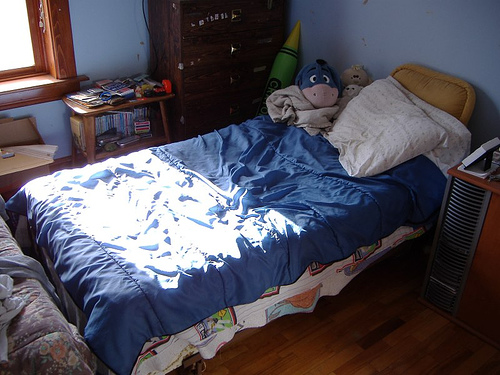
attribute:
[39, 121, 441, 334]
comforter — blue 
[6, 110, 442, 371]
comforter — blue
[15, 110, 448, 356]
mattress — blue 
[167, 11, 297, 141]
dresser — dark brown, tall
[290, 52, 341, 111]
eeyore doll — stuffed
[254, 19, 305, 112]
crayon — large, yellow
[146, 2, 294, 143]
dresser — brown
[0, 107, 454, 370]
bed — child's, messy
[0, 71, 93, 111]
window sill — brown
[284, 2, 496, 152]
wall — blue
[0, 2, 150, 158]
wall — blue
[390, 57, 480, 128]
pillow — yellow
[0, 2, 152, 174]
wall — blue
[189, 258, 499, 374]
flooring — wooden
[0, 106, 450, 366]
sheets — blue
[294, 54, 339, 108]
animal — stuffed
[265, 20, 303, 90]
crayon — oversized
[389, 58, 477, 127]
headboard — small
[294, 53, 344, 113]
eeyore — stuffed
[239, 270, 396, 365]
floor — hardwood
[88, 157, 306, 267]
comforter — blue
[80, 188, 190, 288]
comforter — blue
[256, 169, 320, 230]
comforter — blue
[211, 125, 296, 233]
comforter — blue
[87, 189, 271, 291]
mattress — blue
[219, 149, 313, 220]
mattress — blue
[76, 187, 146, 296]
mattress — blue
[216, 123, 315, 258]
mattress — blue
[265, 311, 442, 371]
floors — brown, hardwood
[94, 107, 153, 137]
books — a row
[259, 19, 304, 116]
crayon — yellow, large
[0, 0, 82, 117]
window frame — brown, wooden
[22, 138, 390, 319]
sheets — blue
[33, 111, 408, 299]
sheets — blue, printed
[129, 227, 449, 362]
sheets — white